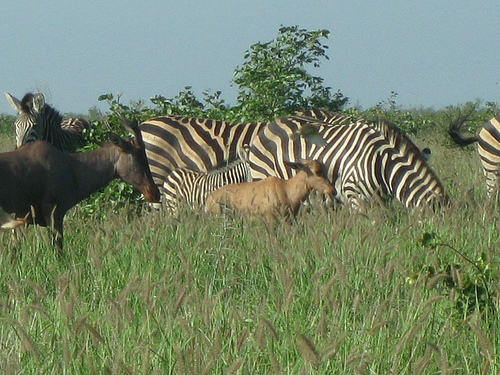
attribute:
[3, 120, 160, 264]
animal — standing, brown, different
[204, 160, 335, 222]
animal — brown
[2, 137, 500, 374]
grass — green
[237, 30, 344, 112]
bush — tall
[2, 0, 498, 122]
sky — blue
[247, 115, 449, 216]
zebra — grazing, standing, eating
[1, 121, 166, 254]
ram — standing, staring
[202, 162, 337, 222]
ram — young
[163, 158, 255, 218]
zebra — young, baby